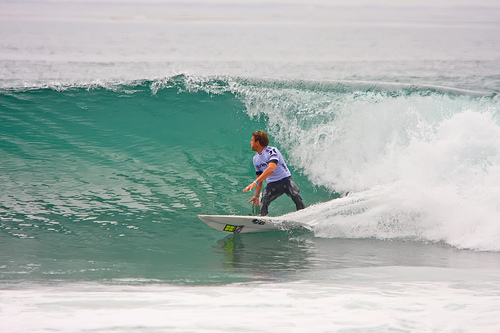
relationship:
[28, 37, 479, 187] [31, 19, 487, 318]
ocean in photo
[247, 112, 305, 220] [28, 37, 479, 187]
surfer in ocean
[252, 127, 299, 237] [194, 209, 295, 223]
man on surfboard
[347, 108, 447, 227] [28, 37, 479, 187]
wave in ocean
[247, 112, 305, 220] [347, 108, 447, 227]
surfer in wave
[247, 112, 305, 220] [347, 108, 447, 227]
surfer riding wave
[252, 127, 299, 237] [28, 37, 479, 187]
man in ocean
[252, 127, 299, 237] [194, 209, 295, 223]
man riding surfboard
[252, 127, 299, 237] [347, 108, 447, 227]
man rides wave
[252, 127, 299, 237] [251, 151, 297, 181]
man wearing shirt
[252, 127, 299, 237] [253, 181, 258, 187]
man wearing watch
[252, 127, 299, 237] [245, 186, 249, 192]
man wearing ring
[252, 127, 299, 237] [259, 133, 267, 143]
man wearing hair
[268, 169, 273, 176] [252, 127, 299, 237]
elbow on man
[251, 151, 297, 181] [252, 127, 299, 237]
top on man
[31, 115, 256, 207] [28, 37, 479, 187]
water in ocean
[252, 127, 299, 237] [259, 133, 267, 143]
man has hair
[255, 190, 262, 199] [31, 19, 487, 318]
band in photo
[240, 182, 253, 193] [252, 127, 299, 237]
hand on man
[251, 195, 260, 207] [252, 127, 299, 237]
hand on man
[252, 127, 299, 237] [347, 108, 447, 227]
man in wave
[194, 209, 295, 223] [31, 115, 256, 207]
surfboard in water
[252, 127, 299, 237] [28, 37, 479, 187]
man surfing in ocean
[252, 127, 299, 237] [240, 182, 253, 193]
man has hand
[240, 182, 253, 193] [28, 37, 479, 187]
hand in ocean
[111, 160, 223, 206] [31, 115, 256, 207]
ripples in water